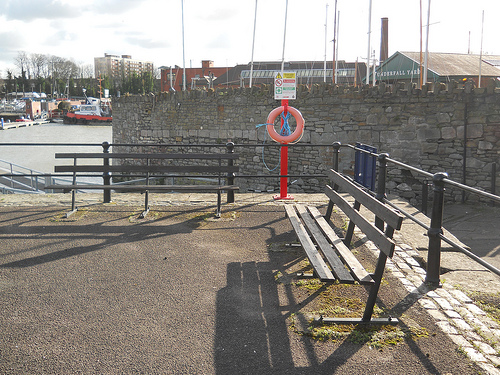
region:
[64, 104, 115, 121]
red and white boat in the harbor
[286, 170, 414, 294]
wood park bench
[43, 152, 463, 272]
two old wood park benches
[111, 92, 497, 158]
crumbling brick wall at harbor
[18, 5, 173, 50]
clouds in the sky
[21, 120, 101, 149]
water in the harbor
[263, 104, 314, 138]
red safety ring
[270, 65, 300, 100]
small sign for safety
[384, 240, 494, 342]
bricks on the ground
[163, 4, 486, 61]
sail boat beams in the back ground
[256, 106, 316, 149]
Orange lifesaver flotation device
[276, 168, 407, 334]
Plain wooden slat bench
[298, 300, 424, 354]
Green moss growing on the ground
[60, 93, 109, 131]
A docked red and white boat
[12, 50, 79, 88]
Barren, brown trees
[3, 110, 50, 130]
A wooden boat dock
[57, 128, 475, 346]
A small pier with two wooden benches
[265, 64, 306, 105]
A water caution sign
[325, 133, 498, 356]
A metal fence with stone paving underneath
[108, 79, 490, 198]
Large stone wall at a boat dock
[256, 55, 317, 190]
sign on a pole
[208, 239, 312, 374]
shadow on the ground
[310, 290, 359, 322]
patch of grass on ground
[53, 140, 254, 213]
bench on the ground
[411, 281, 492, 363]
bricks under a fence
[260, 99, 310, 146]
life preserver on a pole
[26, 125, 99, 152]
water in the background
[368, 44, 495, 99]
top of a building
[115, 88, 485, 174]
brick wall by the water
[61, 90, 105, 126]
boat in the water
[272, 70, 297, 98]
instruction sign on red pole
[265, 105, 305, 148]
orange life ring on red pole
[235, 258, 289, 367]
shadow of bench on concrete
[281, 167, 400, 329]
wood and metal bench on concrete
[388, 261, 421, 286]
brick payvers by wood bench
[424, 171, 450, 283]
black metal fence pole of fence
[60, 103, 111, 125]
white and red boat on water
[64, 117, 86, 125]
tires on side of red boat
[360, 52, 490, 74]
rusty metal roof on green building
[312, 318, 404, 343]
green grass growing under bench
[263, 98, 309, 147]
a red life saver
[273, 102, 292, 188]
a red pole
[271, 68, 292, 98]
a white sign on the pole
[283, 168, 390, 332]
a bench on the ground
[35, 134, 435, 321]
two benches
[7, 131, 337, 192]
a black fence behind the bench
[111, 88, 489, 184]
a stone wall next to the water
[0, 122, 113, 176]
a body of water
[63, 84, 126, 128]
a boat in the water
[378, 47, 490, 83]
the top of a building